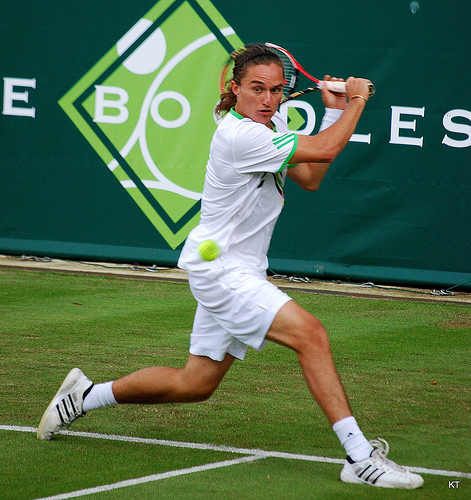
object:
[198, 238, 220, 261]
ball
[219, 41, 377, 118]
racket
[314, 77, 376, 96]
handle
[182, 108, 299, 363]
clothes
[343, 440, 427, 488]
shoe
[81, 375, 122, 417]
socks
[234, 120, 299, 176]
sleeve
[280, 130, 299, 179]
border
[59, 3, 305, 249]
diamond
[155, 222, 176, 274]
air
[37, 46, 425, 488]
man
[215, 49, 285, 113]
hair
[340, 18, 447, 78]
wall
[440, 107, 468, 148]
letters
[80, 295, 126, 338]
grass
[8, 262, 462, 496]
court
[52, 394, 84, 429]
stripes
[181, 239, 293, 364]
shorts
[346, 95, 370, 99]
band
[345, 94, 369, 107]
wrist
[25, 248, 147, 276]
chains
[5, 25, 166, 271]
banner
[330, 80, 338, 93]
tape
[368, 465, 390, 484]
lines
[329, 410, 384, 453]
sock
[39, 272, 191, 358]
field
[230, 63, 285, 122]
face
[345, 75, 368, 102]
hand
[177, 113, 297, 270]
shirt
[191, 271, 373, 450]
legs